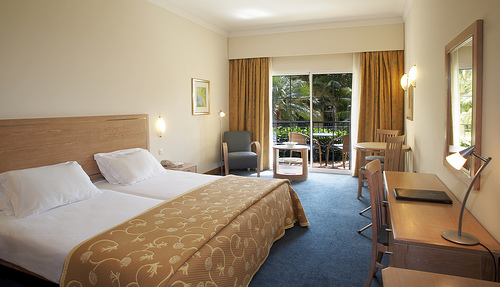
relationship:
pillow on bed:
[11, 146, 117, 238] [2, 113, 291, 285]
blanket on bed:
[64, 177, 304, 283] [2, 153, 291, 285]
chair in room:
[221, 131, 261, 177] [7, 11, 462, 267]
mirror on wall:
[443, 20, 488, 194] [403, 5, 499, 236]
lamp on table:
[440, 145, 493, 246] [370, 162, 498, 283]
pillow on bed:
[93, 148, 168, 186] [2, 162, 321, 285]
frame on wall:
[189, 75, 212, 120] [3, 3, 234, 183]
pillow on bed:
[0, 160, 103, 219] [2, 113, 291, 285]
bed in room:
[2, 113, 291, 285] [1, 1, 498, 285]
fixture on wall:
[394, 60, 436, 126] [69, 25, 166, 77]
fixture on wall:
[400, 64, 416, 122] [405, 23, 446, 173]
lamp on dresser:
[440, 145, 493, 246] [377, 165, 498, 274]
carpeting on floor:
[301, 177, 356, 281] [189, 151, 401, 285]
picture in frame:
[197, 87, 207, 107] [192, 77, 210, 113]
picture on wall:
[197, 87, 207, 107] [0, 1, 228, 170]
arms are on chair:
[214, 138, 267, 149] [213, 119, 268, 174]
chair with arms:
[213, 119, 268, 174] [214, 138, 267, 149]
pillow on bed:
[93, 148, 168, 186] [0, 114, 310, 287]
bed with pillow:
[0, 114, 310, 287] [93, 148, 168, 186]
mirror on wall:
[447, 34, 473, 152] [403, 5, 499, 236]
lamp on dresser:
[448, 147, 495, 248] [377, 165, 498, 274]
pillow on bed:
[94, 151, 166, 174] [43, 79, 340, 285]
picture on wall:
[197, 86, 207, 106] [137, 35, 246, 145]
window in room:
[273, 73, 351, 168] [7, 11, 462, 267]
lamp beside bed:
[137, 105, 192, 170] [14, 127, 284, 268]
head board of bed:
[0, 114, 151, 184] [26, 114, 371, 281]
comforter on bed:
[49, 180, 315, 284] [9, 98, 292, 278]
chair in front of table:
[358, 154, 435, 267] [382, 170, 499, 254]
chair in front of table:
[361, 142, 391, 247] [389, 143, 475, 265]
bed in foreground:
[2, 113, 291, 285] [7, 151, 456, 267]